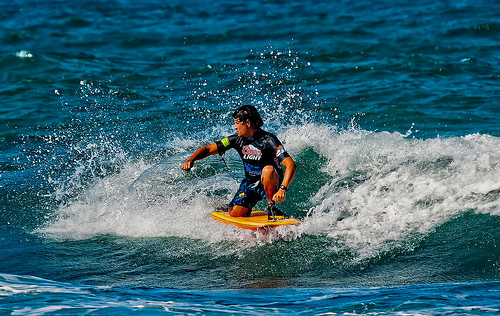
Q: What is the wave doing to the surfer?
A: Splashing all over.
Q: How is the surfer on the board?
A: Kneeling.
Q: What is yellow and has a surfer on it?
A: A board.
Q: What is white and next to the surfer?
A: The waves of the water.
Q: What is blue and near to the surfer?
A: Water.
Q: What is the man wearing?
A: A black wetsuit.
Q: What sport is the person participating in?
A: Surfing.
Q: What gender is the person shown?
A: Male.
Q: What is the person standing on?
A: Surfboard.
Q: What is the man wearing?
A: Wet suit.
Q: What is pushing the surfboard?
A: Waves.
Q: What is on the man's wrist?
A: Watch.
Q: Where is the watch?
A: Left arm.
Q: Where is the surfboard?
A: Water.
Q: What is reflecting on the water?
A: Sun.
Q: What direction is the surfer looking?
A: Left.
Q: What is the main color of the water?
A: Blue.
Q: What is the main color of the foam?
A: White.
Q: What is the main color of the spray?
A: White.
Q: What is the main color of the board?
A: Yellow.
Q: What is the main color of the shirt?
A: Black.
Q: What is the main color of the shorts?
A: Black.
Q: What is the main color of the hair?
A: Black.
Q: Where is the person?
A: On the board.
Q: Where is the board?
A: In the water.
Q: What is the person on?
A: A board.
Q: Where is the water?
A: In the ocean.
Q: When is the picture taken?
A: Daytime.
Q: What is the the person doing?
A: Surfing.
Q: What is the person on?
A: A surfboard.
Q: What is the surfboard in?
A: The ocean.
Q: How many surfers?
A: One.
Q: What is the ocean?
A: A body of water.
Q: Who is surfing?
A: A man.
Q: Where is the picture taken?
A: At the ocean.